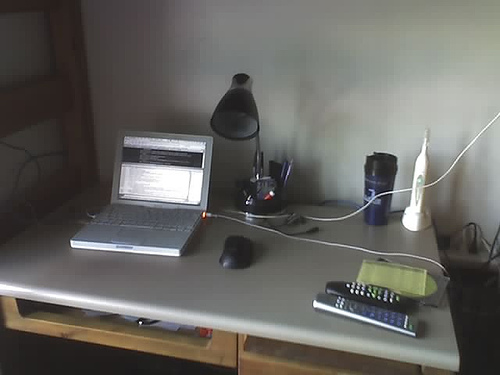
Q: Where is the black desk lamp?
A: Desk.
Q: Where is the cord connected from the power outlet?
A: Laptop.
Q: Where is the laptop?
A: Table.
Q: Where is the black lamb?
A: Table.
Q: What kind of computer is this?
A: A laptop.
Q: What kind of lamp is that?
A: A black lamp.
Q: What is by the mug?
A: A toothbrush.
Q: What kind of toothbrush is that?
A: An electric toothbrush.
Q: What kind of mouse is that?
A: A wireless black mouse.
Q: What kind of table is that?
A: A white table.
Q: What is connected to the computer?
A: Cables.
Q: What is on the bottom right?
A: Remote controls.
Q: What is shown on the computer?
A: Black and white text.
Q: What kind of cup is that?
A: A large blue mug.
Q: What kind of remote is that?
A: A small black remote control.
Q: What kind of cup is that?
A: A large blue mug.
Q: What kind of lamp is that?
A: A small black lamp.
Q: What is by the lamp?
A: Pens.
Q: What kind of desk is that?
A: A white wooden desk.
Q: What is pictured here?
A: Desk.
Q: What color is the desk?
A: Beige and white.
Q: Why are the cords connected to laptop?
A: To charge it.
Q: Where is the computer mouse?
A: To the right of laptop.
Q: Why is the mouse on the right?
A: User is right-handed.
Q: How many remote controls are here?
A: Two.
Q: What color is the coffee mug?
A: Blue.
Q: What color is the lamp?
A: Black.